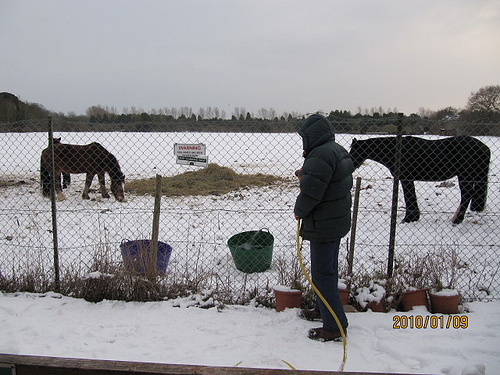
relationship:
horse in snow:
[38, 138, 132, 208] [0, 129, 497, 371]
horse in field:
[40, 142, 125, 202] [0, 132, 500, 374]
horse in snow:
[40, 142, 125, 202] [0, 129, 497, 371]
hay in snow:
[127, 162, 268, 191] [59, 311, 204, 348]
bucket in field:
[116, 234, 176, 280] [10, 131, 498, 288]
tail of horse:
[473, 140, 484, 219] [348, 132, 491, 224]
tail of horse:
[39, 150, 60, 196] [33, 140, 127, 202]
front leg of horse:
[96, 169, 110, 201] [38, 138, 132, 208]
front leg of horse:
[81, 163, 101, 201] [348, 132, 491, 224]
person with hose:
[293, 114, 356, 342] [286, 168, 352, 373]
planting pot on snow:
[426, 288, 460, 313] [0, 129, 497, 371]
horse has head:
[349, 135, 491, 227] [350, 137, 364, 168]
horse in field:
[348, 132, 491, 224] [78, 122, 298, 158]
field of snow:
[78, 122, 298, 158] [202, 308, 255, 359]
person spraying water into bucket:
[283, 110, 357, 340] [232, 226, 281, 281]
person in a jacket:
[293, 114, 356, 342] [301, 113, 350, 233]